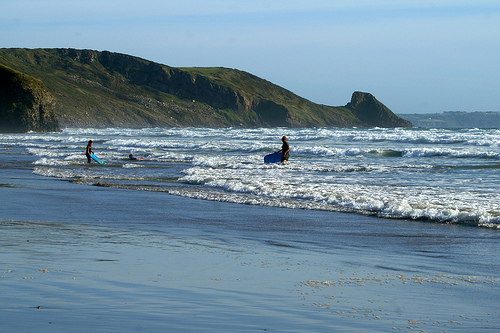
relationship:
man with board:
[278, 136, 290, 165] [262, 151, 288, 165]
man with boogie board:
[85, 140, 95, 163] [89, 150, 104, 165]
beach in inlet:
[2, 136, 498, 331] [3, 5, 495, 281]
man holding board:
[278, 136, 290, 165] [86, 143, 121, 178]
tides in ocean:
[293, 127, 333, 139] [1, 129, 498, 331]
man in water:
[278, 136, 290, 165] [1, 122, 499, 246]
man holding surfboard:
[278, 136, 290, 165] [261, 149, 286, 165]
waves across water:
[46, 127, 484, 207] [29, 110, 499, 264]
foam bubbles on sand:
[180, 134, 267, 221] [15, 214, 498, 330]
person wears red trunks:
[122, 150, 142, 166] [135, 152, 155, 172]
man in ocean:
[278, 136, 290, 165] [1, 129, 498, 331]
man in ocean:
[264, 124, 295, 171] [99, 111, 478, 221]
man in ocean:
[79, 134, 104, 175] [99, 111, 478, 221]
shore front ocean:
[17, 246, 497, 331] [64, 88, 497, 318]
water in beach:
[43, 197, 405, 317] [15, 124, 495, 231]